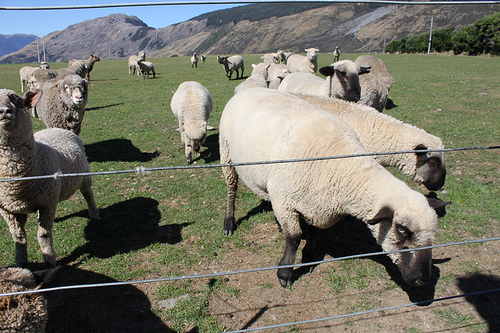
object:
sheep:
[217, 87, 450, 287]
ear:
[413, 143, 426, 158]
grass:
[0, 51, 498, 332]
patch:
[207, 275, 240, 296]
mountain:
[0, 13, 206, 63]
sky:
[0, 0, 269, 38]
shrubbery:
[383, 37, 406, 54]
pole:
[426, 15, 434, 54]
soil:
[129, 222, 498, 333]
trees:
[447, 22, 468, 54]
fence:
[0, 145, 499, 332]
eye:
[393, 221, 408, 238]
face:
[383, 214, 432, 286]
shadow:
[50, 196, 198, 264]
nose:
[433, 185, 440, 190]